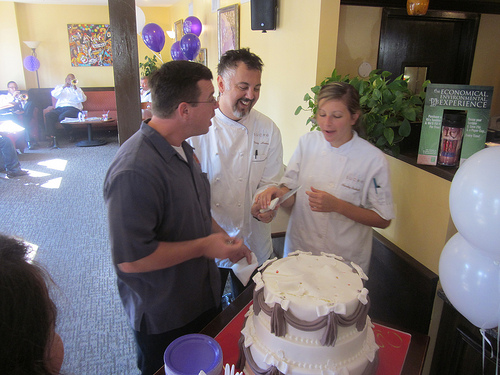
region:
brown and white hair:
[214, 50, 272, 92]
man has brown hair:
[157, 59, 212, 107]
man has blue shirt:
[123, 138, 250, 310]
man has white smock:
[188, 116, 283, 269]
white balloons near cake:
[431, 154, 496, 339]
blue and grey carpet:
[37, 196, 102, 261]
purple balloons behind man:
[135, 13, 198, 57]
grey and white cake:
[244, 239, 381, 374]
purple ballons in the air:
[142, 16, 206, 60]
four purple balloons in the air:
[143, 15, 208, 60]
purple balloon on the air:
[139, 20, 167, 63]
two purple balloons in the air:
[178, 13, 203, 64]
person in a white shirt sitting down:
[37, 72, 89, 147]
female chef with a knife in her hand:
[249, 80, 398, 275]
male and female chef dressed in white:
[185, 44, 397, 276]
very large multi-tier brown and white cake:
[231, 245, 387, 373]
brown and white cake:
[238, 245, 381, 374]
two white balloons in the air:
[433, 140, 499, 374]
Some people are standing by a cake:
[100, 20, 481, 370]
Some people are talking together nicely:
[100, 38, 435, 354]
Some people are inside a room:
[96, 40, 461, 366]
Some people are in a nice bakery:
[95, 18, 461, 351]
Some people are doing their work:
[110, 30, 497, 365]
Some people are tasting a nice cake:
[118, 20, 458, 368]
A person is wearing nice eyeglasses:
[105, 15, 480, 353]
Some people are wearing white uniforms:
[138, 26, 478, 358]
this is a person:
[102, 61, 244, 364]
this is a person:
[254, 80, 394, 332]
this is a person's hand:
[105, 170, 242, 272]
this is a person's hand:
[305, 155, 395, 227]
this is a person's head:
[150, 64, 221, 135]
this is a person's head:
[218, 48, 266, 121]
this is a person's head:
[311, 81, 358, 141]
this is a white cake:
[231, 245, 381, 373]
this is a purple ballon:
[138, 20, 168, 56]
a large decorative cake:
[242, 253, 375, 373]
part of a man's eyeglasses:
[187, 94, 216, 109]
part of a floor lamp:
[22, 35, 44, 87]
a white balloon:
[436, 233, 498, 333]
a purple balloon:
[138, 22, 167, 59]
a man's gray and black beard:
[229, 95, 254, 118]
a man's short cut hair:
[147, 60, 214, 122]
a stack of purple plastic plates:
[162, 328, 226, 374]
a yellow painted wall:
[267, 30, 311, 110]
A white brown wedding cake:
[243, 228, 425, 372]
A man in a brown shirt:
[95, 76, 226, 344]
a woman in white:
[276, 90, 411, 297]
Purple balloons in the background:
[32, 23, 207, 53]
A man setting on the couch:
[28, 63, 118, 174]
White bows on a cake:
[299, 303, 366, 335]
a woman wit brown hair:
[302, 69, 382, 154]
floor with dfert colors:
[13, 173, 108, 297]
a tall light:
[18, 26, 53, 140]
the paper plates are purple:
[162, 334, 225, 374]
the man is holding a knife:
[187, 46, 280, 303]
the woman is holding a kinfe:
[271, 80, 392, 277]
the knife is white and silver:
[249, 186, 301, 212]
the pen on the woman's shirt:
[370, 177, 384, 194]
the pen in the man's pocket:
[250, 145, 260, 165]